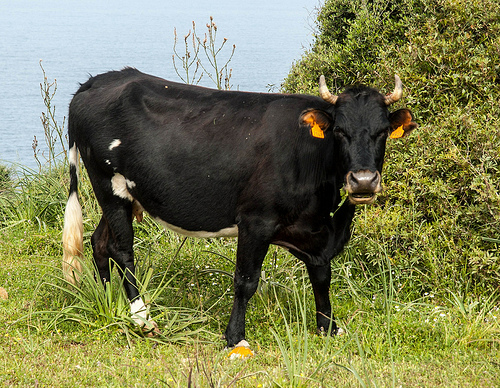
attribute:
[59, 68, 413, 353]
bull — grazing, white, black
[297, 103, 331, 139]
ear — tagged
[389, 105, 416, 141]
ear — tagged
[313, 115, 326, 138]
id tag — orange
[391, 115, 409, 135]
id tag — orange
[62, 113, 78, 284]
tail — white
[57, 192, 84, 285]
hair — white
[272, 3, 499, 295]
tree — thick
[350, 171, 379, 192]
nose — gray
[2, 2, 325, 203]
stream — blue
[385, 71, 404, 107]
horn — white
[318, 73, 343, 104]
horn — white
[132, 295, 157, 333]
foot — white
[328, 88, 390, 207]
head — lookin forward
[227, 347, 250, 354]
id tag — yellow